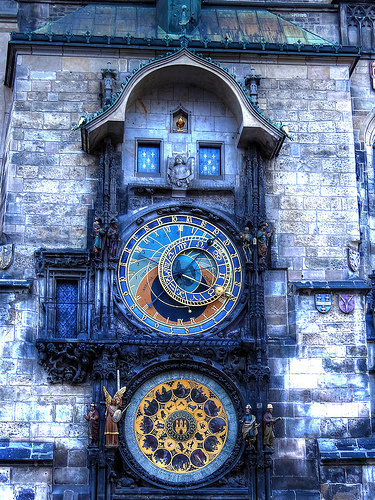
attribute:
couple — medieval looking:
[311, 289, 356, 319]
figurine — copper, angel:
[101, 385, 131, 445]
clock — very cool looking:
[117, 202, 254, 326]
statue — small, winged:
[100, 383, 126, 446]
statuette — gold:
[170, 110, 191, 133]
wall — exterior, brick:
[0, 53, 374, 499]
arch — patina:
[82, 41, 288, 147]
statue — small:
[224, 206, 282, 277]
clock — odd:
[109, 358, 252, 487]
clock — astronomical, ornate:
[122, 210, 243, 336]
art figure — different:
[240, 225, 252, 265]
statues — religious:
[102, 385, 130, 447]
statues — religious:
[82, 399, 99, 447]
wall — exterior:
[0, 0, 366, 499]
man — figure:
[82, 402, 102, 443]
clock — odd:
[112, 205, 255, 341]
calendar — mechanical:
[115, 210, 245, 337]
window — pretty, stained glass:
[138, 139, 157, 176]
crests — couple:
[311, 292, 359, 313]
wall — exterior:
[22, 51, 353, 488]